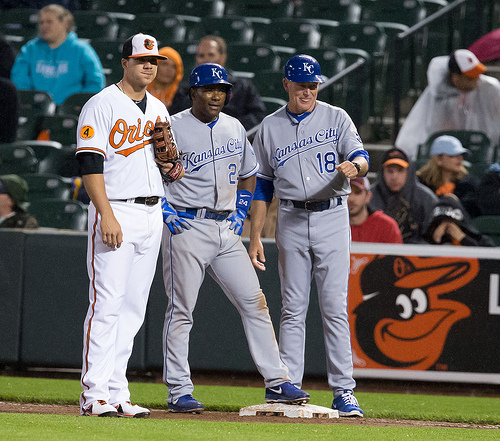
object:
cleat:
[272, 393, 310, 407]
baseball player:
[74, 32, 183, 418]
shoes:
[163, 391, 203, 413]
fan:
[393, 46, 499, 159]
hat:
[445, 48, 488, 81]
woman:
[10, 4, 108, 107]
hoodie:
[11, 32, 108, 105]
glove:
[223, 188, 250, 234]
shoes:
[78, 399, 117, 419]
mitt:
[150, 121, 184, 185]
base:
[232, 399, 342, 421]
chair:
[257, 20, 318, 50]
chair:
[117, 12, 188, 44]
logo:
[108, 116, 166, 158]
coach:
[246, 53, 370, 421]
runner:
[158, 63, 311, 414]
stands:
[0, 0, 500, 264]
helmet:
[190, 63, 236, 89]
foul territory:
[0, 373, 499, 425]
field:
[0, 371, 500, 441]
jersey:
[74, 83, 177, 201]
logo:
[344, 251, 499, 374]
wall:
[0, 229, 499, 388]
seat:
[190, 15, 255, 45]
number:
[80, 127, 89, 139]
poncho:
[391, 54, 497, 160]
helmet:
[283, 54, 327, 85]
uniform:
[152, 63, 292, 406]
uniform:
[75, 81, 178, 415]